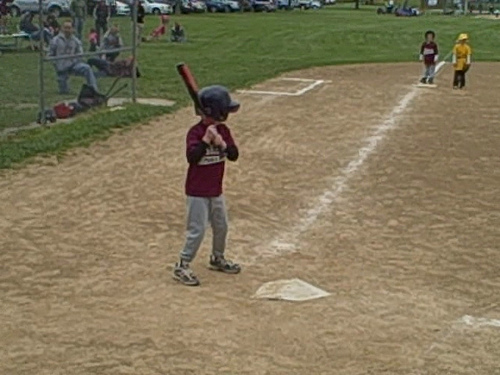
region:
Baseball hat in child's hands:
[168, 57, 228, 150]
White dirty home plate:
[250, 269, 335, 310]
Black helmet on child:
[181, 79, 241, 120]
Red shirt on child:
[176, 116, 242, 205]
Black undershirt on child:
[185, 137, 242, 172]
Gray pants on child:
[175, 192, 235, 263]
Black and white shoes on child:
[162, 252, 247, 287]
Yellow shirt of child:
[447, 42, 472, 74]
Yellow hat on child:
[452, 29, 469, 42]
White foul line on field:
[246, 58, 478, 260]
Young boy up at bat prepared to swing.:
[170, 61, 240, 286]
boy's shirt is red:
[182, 123, 239, 199]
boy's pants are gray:
[167, 186, 243, 281]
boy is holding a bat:
[147, 57, 240, 168]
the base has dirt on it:
[227, 235, 362, 333]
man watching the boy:
[42, 6, 121, 107]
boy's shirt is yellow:
[450, 35, 475, 75]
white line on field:
[235, 66, 492, 231]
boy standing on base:
[394, 18, 446, 87]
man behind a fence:
[15, 11, 108, 81]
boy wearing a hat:
[440, 15, 468, 53]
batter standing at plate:
[171, 59, 243, 285]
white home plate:
[253, 278, 325, 303]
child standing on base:
[419, 30, 439, 82]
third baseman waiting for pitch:
[448, 33, 472, 88]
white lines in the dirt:
[251, 60, 499, 335]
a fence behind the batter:
[1, 0, 140, 128]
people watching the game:
[9, 0, 187, 93]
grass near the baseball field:
[0, 0, 498, 166]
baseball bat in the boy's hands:
[176, 59, 218, 139]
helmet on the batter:
[194, 85, 238, 119]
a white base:
[250, 268, 330, 304]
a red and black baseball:
[175, 55, 215, 135]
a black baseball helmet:
[195, 77, 242, 121]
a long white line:
[234, 48, 458, 278]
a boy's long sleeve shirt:
[182, 115, 242, 199]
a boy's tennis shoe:
[165, 260, 207, 290]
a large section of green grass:
[0, 4, 497, 165]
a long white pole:
[37, 43, 136, 65]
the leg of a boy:
[205, 196, 232, 255]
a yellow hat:
[457, 30, 467, 40]